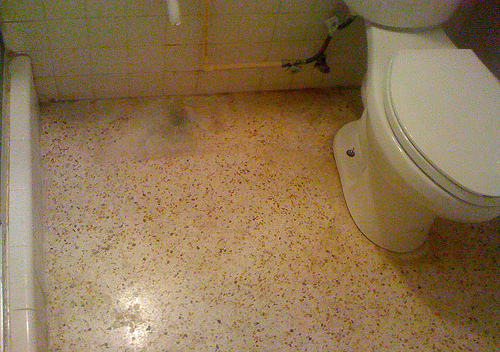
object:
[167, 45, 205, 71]
tile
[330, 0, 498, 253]
toilet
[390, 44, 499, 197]
toilet lid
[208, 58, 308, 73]
pipe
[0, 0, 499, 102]
wall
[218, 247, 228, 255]
speck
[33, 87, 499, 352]
floor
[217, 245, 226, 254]
speck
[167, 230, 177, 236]
speck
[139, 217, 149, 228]
speck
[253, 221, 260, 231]
speck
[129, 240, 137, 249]
speck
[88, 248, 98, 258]
speck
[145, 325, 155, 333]
speck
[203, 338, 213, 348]
speck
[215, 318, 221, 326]
speck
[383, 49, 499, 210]
seat